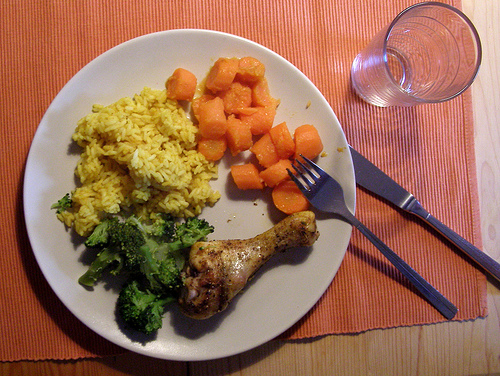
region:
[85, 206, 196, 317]
Green broccoli tops in a creamy sauce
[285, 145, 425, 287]
A fork resting on a plate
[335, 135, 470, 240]
A knife laying beside a plate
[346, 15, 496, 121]
An empty glass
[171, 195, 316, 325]
A deliciously seasoned chicken leg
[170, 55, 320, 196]
Tasty carrots in a succulent sauce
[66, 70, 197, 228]
Sticky yellow rice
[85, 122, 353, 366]
A white plate holding a tasty meal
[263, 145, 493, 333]
A pink placemat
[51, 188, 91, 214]
A small piece of broccoli hiding in the rice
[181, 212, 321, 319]
a piece of chicken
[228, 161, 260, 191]
a piece of carrot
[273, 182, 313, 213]
a piece of carrot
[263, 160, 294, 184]
a piece of carrot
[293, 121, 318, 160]
a piece of carrot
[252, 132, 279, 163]
a piece of carrot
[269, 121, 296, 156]
a piece of carrot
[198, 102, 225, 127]
a piece of carrot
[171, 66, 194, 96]
a piece of carrot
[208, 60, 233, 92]
a piece of carrot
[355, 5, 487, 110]
Tall glass of table mate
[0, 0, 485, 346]
Orange place mate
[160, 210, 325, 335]
Baked chicken leg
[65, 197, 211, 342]
Green vegetables on white plate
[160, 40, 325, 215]
Steamed carrots on plate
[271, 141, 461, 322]
Fork on plate and placemat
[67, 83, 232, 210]
rice on white plate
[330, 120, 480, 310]
Knife laying on orange placemat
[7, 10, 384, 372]
White dinner plate with complete meal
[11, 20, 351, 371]
White dinner plate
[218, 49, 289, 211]
A group of cooked carrots.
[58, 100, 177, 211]
rice on a plate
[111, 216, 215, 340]
Broccoli on a plate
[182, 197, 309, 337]
Chicken leg on a plate.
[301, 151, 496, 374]
Silver fork and knife.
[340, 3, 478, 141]
A glass on a table.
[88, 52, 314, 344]
Food on a plate.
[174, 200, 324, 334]
Chicken leg with seasoning.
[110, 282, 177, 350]
One green broccolli floret.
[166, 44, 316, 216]
Cut up orange carrots.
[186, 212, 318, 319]
cooked chicken leg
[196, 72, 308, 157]
diced carrots on a white plate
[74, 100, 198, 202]
yellow grains of rice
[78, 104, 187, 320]
yellow rice and broccoli on a white plate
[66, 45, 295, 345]
a plate of yellow rice, broccoli, chicken, and carrots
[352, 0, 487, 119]
empty glass cup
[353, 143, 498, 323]
utensils on orange mat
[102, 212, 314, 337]
broccoli and chicken on a plate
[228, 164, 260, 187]
diced piece of carrot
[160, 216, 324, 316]
well seasoned chicken near broccoli